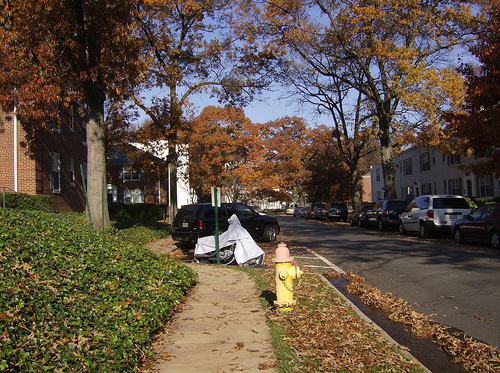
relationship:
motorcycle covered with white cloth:
[187, 209, 274, 271] [192, 208, 267, 255]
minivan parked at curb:
[394, 187, 477, 239] [294, 187, 492, 221]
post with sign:
[209, 180, 227, 267] [208, 183, 224, 212]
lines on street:
[299, 237, 352, 276] [301, 206, 499, 366]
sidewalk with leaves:
[159, 258, 271, 372] [187, 264, 261, 367]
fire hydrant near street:
[265, 235, 311, 316] [301, 206, 499, 366]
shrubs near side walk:
[114, 197, 165, 232] [159, 258, 271, 372]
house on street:
[0, 80, 85, 199] [301, 206, 499, 366]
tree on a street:
[315, 4, 486, 193] [301, 206, 499, 366]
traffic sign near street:
[209, 180, 227, 267] [301, 206, 499, 366]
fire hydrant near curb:
[265, 235, 311, 316] [287, 228, 407, 373]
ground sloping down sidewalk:
[301, 206, 499, 366] [159, 258, 271, 372]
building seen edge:
[0, 80, 85, 199] [20, 140, 49, 194]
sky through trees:
[113, 1, 480, 125] [6, 4, 494, 167]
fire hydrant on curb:
[265, 235, 311, 316] [314, 269, 438, 372]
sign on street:
[208, 183, 224, 212] [301, 206, 499, 366]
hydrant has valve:
[265, 235, 311, 316] [278, 269, 292, 281]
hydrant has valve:
[265, 235, 311, 316] [295, 265, 305, 282]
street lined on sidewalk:
[299, 237, 352, 276] [301, 206, 499, 366]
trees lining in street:
[6, 4, 494, 167] [301, 206, 499, 366]